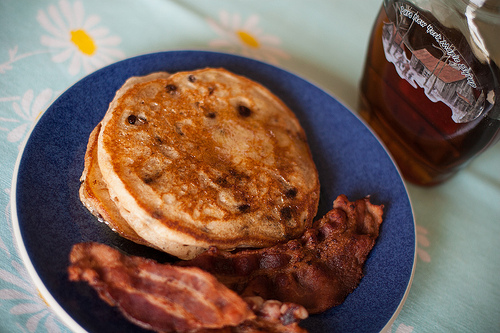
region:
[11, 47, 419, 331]
breakfast on a blue plate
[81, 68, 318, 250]
pancakes with blueberries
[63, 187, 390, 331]
two slices of bacon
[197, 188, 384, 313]
a crisp slice of bacon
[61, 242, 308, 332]
a chewy slice of bacon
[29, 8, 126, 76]
a white daisy with a yellow center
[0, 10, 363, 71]
a light blue tablecloth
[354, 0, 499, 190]
a bottle of real maple syrup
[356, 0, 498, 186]
maple syrup from New York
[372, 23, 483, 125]
an illustration of a cabin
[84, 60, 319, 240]
two pancakes on plate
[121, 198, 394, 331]
cooked bacon on plate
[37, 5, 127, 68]
white flower on tablecloth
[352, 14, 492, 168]
bottle of maple syrup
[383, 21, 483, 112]
illustration on syrup bottle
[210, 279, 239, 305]
fat in strip of bacon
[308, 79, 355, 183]
blue plate containing food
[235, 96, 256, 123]
chocolate chip in pancake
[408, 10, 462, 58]
words on syrup bottle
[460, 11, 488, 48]
reflection on syrup bottle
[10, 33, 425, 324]
blue plate with bacon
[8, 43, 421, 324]
blue plate with pancakes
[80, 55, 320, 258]
brown chocolate chip pancakes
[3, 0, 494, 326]
this is an indoor breakfast scene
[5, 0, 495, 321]
blue white flowered table cloth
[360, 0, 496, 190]
glass bottle of maple syrup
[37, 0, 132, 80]
white daisy flower with yellow center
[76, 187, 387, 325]
two slices of crispy bacon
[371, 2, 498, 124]
red and white label on syrup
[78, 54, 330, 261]
two pancakes with syrup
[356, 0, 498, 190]
A bottle of syrup on the table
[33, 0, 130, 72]
A white flower with a yellow center on a tablecloth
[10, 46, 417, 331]
A blue plate with food on it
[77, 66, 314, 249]
Two pancakes on the plate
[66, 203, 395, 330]
Two strips of bacon underneath the pancakes on the plate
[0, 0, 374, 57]
A light blue floral tablecloth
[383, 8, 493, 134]
An image on the syrup bottle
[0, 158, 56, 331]
The edge of the plate trimmed in white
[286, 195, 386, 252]
A wrinkly part of the bacon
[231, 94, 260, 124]
A black dot on the pancake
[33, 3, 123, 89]
daisy on table cloth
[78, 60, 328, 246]
two blueberry pancakes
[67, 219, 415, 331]
two pieces of cooked bacon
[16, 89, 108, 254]
ceramic blue plate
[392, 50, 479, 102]
picture of log cabin on syrup bottle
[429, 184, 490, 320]
baby blue table cloth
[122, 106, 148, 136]
blueberry in the pancake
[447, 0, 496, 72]
reflection of light on the syrup bottle